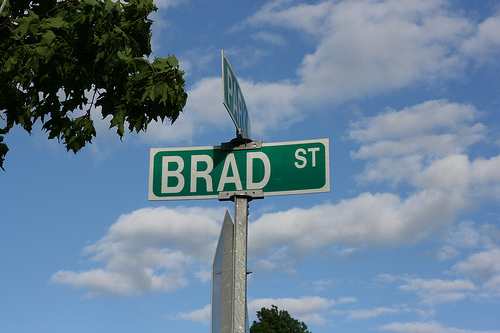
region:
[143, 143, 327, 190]
Sign that says Brad St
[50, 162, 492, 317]
Sky is light blue and cloudy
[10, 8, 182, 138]
Tree is green and leafy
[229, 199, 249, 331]
Metal pole is gray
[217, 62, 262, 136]
Green sign pointing different direction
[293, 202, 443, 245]
Long cloud in sky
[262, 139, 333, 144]
Border of sign is white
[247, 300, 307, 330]
Tree beyond sign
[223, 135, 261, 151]
Gray metal clasp on sign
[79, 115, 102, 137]
Individual leaf on tree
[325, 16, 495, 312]
the clouds in the sky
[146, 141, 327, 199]
the bottom green sign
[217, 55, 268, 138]
the top green sign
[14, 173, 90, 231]
the clear blue sky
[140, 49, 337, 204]
the two green signs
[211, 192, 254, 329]
the silver street sign pole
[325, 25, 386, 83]
the white cloud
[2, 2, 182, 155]
the leaves on the tree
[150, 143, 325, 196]
the BRAD ST sign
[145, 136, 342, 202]
the white lining on the sign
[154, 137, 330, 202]
green brad st sign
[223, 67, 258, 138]
green sign on brad sign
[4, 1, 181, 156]
green leaves in the left side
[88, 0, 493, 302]
white clouds in blue clear sky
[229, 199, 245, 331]
white pole where signs are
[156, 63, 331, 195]
two green signs in white pole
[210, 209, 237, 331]
gray part of the back of a sign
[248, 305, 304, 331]
green leaves under signs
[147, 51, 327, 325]
three signs in a white pole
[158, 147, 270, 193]
brad white letters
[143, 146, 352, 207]
green and white street sign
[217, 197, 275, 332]
metal street sign pole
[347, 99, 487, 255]
white cloud in blue sky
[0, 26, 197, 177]
tall green trees hanging in sky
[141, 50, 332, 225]
two green and white street signs on street sign pole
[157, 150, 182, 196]
white lettering on green street sign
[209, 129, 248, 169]
shadow of top green sign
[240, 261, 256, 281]
bolt on street sign pole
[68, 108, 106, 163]
green leaves on green tree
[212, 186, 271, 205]
metal strip holding street sign to metal pole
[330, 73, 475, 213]
the sky is clear and cloudy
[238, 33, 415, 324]
the sky is clear and cloudy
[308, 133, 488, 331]
the sky is clear and cloudy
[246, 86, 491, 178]
the sky is clear and cloudy